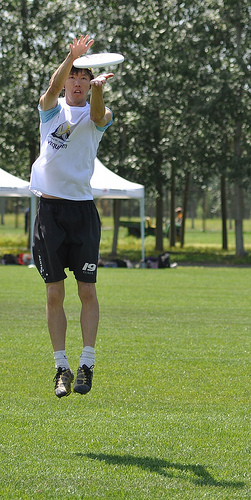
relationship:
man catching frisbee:
[29, 31, 126, 397] [70, 51, 124, 69]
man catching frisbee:
[29, 32, 113, 399] [72, 52, 123, 69]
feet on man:
[44, 350, 104, 394] [6, 36, 104, 412]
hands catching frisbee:
[65, 30, 115, 91] [69, 51, 127, 68]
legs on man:
[46, 280, 99, 357] [39, 54, 111, 183]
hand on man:
[86, 71, 116, 91] [22, 25, 117, 402]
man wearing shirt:
[29, 32, 113, 399] [28, 98, 110, 200]